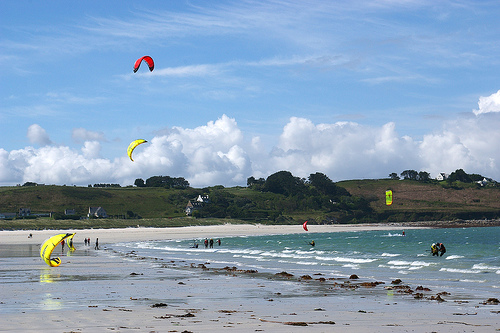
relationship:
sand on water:
[11, 221, 496, 330] [35, 296, 60, 308]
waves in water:
[136, 245, 491, 287] [107, 226, 497, 293]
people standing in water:
[427, 237, 452, 260] [229, 235, 291, 255]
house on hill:
[434, 170, 446, 181] [1, 176, 498, 228]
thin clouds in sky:
[5, 7, 480, 105] [0, 2, 497, 170]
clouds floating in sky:
[7, 87, 495, 194] [0, 2, 497, 170]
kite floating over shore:
[133, 55, 154, 73] [0, 219, 499, 329]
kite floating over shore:
[127, 139, 148, 162] [0, 219, 499, 329]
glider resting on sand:
[39, 233, 73, 267] [68, 273, 373, 331]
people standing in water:
[195, 236, 221, 248] [107, 223, 498, 287]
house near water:
[179, 189, 215, 223] [3, 238, 499, 328]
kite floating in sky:
[132, 53, 153, 72] [0, 2, 497, 170]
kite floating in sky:
[125, 137, 149, 162] [0, 2, 497, 170]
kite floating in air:
[133, 55, 154, 73] [1, 0, 499, 188]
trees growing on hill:
[389, 160, 474, 190] [0, 169, 500, 230]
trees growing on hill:
[149, 177, 188, 185] [0, 169, 500, 230]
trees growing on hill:
[134, 175, 145, 187] [0, 169, 500, 230]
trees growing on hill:
[92, 181, 118, 188] [0, 169, 500, 230]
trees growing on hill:
[25, 179, 35, 184] [0, 169, 500, 230]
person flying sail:
[309, 240, 316, 247] [303, 220, 308, 231]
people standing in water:
[427, 236, 449, 260] [337, 235, 497, 280]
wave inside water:
[328, 224, 408, 277] [2, 228, 499, 308]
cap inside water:
[445, 249, 466, 261] [2, 228, 499, 308]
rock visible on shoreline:
[347, 272, 359, 280] [106, 224, 498, 304]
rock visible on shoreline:
[388, 275, 403, 284] [106, 224, 498, 304]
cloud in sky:
[471, 90, 498, 116] [0, 2, 497, 170]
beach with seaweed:
[0, 222, 499, 330] [282, 315, 310, 329]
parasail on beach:
[38, 230, 74, 270] [6, 185, 492, 331]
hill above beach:
[213, 179, 488, 220] [91, 219, 495, 302]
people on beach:
[59, 236, 102, 251] [0, 222, 499, 330]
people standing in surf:
[140, 205, 257, 265] [196, 246, 225, 253]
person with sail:
[302, 236, 317, 251] [300, 217, 311, 234]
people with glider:
[430, 243, 439, 257] [385, 189, 393, 206]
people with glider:
[193, 235, 226, 249] [39, 233, 73, 267]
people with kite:
[65, 233, 102, 249] [133, 55, 154, 73]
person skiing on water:
[396, 223, 406, 237] [2, 228, 499, 308]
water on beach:
[1, 245, 161, 331] [0, 222, 499, 330]